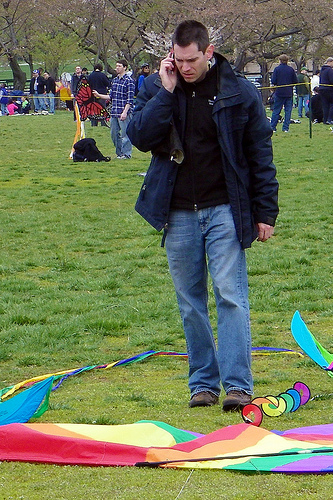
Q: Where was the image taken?
A: It was taken at the field.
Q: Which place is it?
A: It is a field.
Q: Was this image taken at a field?
A: Yes, it was taken in a field.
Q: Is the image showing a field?
A: Yes, it is showing a field.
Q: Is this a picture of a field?
A: Yes, it is showing a field.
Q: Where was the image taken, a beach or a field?
A: It was taken at a field.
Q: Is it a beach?
A: No, it is a field.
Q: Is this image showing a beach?
A: No, the picture is showing a field.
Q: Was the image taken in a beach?
A: No, the picture was taken in a field.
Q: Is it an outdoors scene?
A: Yes, it is outdoors.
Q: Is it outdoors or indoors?
A: It is outdoors.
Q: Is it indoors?
A: No, it is outdoors.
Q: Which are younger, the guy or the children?
A: The children are younger than the guy.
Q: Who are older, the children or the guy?
A: The guy are older than the children.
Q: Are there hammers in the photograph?
A: No, there are no hammers.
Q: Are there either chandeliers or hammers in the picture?
A: No, there are no hammers or chandeliers.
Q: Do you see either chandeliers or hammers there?
A: No, there are no hammers or chandeliers.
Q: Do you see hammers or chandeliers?
A: No, there are no hammers or chandeliers.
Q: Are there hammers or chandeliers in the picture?
A: No, there are no hammers or chandeliers.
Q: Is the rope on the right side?
A: Yes, the rope is on the right of the image.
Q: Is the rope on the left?
A: No, the rope is on the right of the image.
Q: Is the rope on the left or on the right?
A: The rope is on the right of the image.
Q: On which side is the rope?
A: The rope is on the right of the image.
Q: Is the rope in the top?
A: Yes, the rope is in the top of the image.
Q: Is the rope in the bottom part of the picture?
A: No, the rope is in the top of the image.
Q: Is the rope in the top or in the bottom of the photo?
A: The rope is in the top of the image.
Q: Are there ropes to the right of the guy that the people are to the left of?
A: Yes, there is a rope to the right of the guy.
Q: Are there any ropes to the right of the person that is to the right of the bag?
A: Yes, there is a rope to the right of the guy.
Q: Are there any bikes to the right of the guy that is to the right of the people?
A: No, there is a rope to the right of the guy.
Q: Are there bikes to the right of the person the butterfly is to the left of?
A: No, there is a rope to the right of the guy.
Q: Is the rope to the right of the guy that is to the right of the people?
A: Yes, the rope is to the right of the guy.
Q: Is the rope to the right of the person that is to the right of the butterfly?
A: Yes, the rope is to the right of the guy.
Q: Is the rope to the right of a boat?
A: No, the rope is to the right of the guy.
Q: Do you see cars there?
A: No, there are no cars.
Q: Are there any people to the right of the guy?
A: Yes, there are people to the right of the guy.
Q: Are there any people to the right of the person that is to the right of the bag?
A: Yes, there are people to the right of the guy.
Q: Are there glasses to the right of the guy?
A: No, there are people to the right of the guy.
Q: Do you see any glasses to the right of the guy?
A: No, there are people to the right of the guy.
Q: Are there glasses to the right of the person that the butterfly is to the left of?
A: No, there are people to the right of the guy.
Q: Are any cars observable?
A: No, there are no cars.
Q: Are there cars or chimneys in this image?
A: No, there are no cars or chimneys.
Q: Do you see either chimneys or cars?
A: No, there are no cars or chimneys.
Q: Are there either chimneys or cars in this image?
A: No, there are no cars or chimneys.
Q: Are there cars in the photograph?
A: No, there are no cars.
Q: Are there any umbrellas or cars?
A: No, there are no cars or umbrellas.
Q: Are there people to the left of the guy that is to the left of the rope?
A: Yes, there are people to the left of the guy.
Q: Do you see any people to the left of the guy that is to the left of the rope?
A: Yes, there are people to the left of the guy.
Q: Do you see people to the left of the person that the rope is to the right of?
A: Yes, there are people to the left of the guy.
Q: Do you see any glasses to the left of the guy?
A: No, there are people to the left of the guy.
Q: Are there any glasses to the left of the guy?
A: No, there are people to the left of the guy.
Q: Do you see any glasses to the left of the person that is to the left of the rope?
A: No, there are people to the left of the guy.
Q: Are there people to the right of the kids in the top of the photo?
A: Yes, there are people to the right of the children.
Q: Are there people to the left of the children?
A: No, the people are to the right of the children.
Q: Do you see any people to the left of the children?
A: No, the people are to the right of the children.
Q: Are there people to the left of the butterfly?
A: Yes, there are people to the left of the butterfly.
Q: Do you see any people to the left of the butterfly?
A: Yes, there are people to the left of the butterfly.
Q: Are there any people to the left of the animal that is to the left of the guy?
A: Yes, there are people to the left of the butterfly.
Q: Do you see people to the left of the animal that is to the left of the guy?
A: Yes, there are people to the left of the butterfly.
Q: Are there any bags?
A: Yes, there is a bag.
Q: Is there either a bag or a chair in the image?
A: Yes, there is a bag.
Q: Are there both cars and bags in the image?
A: No, there is a bag but no cars.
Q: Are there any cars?
A: No, there are no cars.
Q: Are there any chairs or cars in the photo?
A: No, there are no cars or chairs.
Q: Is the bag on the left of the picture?
A: Yes, the bag is on the left of the image.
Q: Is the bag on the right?
A: No, the bag is on the left of the image.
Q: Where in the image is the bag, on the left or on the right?
A: The bag is on the left of the image.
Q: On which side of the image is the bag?
A: The bag is on the left of the image.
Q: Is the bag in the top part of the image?
A: Yes, the bag is in the top of the image.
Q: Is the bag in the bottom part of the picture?
A: No, the bag is in the top of the image.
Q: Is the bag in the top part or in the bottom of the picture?
A: The bag is in the top of the image.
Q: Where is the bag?
A: The bag is on the ground.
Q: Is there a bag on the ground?
A: Yes, there is a bag on the ground.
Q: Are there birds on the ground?
A: No, there is a bag on the ground.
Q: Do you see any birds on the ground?
A: No, there is a bag on the ground.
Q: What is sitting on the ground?
A: The bag is sitting on the ground.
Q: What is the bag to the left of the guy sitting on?
A: The bag is sitting on the ground.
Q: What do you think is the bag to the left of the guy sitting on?
A: The bag is sitting on the ground.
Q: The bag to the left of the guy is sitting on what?
A: The bag is sitting on the ground.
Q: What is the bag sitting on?
A: The bag is sitting on the ground.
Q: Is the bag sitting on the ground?
A: Yes, the bag is sitting on the ground.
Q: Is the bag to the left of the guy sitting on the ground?
A: Yes, the bag is sitting on the ground.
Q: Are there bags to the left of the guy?
A: Yes, there is a bag to the left of the guy.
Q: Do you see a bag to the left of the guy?
A: Yes, there is a bag to the left of the guy.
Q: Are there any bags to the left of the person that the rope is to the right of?
A: Yes, there is a bag to the left of the guy.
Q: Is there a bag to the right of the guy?
A: No, the bag is to the left of the guy.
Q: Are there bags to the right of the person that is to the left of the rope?
A: No, the bag is to the left of the guy.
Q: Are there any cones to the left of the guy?
A: No, there is a bag to the left of the guy.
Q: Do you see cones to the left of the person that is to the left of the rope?
A: No, there is a bag to the left of the guy.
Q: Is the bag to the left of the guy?
A: Yes, the bag is to the left of the guy.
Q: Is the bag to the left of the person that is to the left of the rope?
A: Yes, the bag is to the left of the guy.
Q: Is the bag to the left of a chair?
A: No, the bag is to the left of the guy.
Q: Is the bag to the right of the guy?
A: No, the bag is to the left of the guy.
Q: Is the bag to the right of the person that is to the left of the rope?
A: No, the bag is to the left of the guy.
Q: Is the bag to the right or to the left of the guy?
A: The bag is to the left of the guy.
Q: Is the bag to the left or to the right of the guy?
A: The bag is to the left of the guy.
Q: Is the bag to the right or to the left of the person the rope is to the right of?
A: The bag is to the left of the guy.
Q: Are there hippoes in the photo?
A: No, there are no hippoes.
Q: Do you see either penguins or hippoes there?
A: No, there are no hippoes or penguins.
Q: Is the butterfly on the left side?
A: Yes, the butterfly is on the left of the image.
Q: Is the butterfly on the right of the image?
A: No, the butterfly is on the left of the image.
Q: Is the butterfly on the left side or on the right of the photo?
A: The butterfly is on the left of the image.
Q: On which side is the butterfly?
A: The butterfly is on the left of the image.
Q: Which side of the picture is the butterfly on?
A: The butterfly is on the left of the image.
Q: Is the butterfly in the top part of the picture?
A: Yes, the butterfly is in the top of the image.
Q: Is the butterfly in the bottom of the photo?
A: No, the butterfly is in the top of the image.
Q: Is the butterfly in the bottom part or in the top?
A: The butterfly is in the top of the image.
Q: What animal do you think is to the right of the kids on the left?
A: The animal is a butterfly.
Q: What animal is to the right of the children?
A: The animal is a butterfly.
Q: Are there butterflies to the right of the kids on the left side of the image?
A: Yes, there is a butterfly to the right of the kids.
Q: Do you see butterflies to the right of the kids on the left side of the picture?
A: Yes, there is a butterfly to the right of the kids.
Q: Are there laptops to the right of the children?
A: No, there is a butterfly to the right of the children.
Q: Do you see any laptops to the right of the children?
A: No, there is a butterfly to the right of the children.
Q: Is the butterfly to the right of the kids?
A: Yes, the butterfly is to the right of the kids.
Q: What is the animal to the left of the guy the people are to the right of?
A: The animal is a butterfly.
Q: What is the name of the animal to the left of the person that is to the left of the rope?
A: The animal is a butterfly.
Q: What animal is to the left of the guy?
A: The animal is a butterfly.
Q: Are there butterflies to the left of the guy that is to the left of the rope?
A: Yes, there is a butterfly to the left of the guy.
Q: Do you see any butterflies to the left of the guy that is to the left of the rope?
A: Yes, there is a butterfly to the left of the guy.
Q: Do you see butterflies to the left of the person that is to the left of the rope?
A: Yes, there is a butterfly to the left of the guy.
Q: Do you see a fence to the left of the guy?
A: No, there is a butterfly to the left of the guy.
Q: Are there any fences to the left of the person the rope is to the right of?
A: No, there is a butterfly to the left of the guy.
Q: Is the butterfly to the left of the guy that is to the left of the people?
A: Yes, the butterfly is to the left of the guy.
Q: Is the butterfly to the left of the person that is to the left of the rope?
A: Yes, the butterfly is to the left of the guy.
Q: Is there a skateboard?
A: No, there are no skateboards.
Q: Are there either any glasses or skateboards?
A: No, there are no skateboards or glasses.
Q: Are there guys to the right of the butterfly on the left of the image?
A: Yes, there is a guy to the right of the butterfly.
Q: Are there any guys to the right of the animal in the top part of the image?
A: Yes, there is a guy to the right of the butterfly.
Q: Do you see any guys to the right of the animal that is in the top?
A: Yes, there is a guy to the right of the butterfly.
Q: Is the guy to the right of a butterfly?
A: Yes, the guy is to the right of a butterfly.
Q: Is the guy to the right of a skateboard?
A: No, the guy is to the right of a butterfly.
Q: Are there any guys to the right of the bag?
A: Yes, there is a guy to the right of the bag.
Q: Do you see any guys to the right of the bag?
A: Yes, there is a guy to the right of the bag.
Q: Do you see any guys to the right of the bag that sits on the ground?
A: Yes, there is a guy to the right of the bag.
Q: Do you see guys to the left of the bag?
A: No, the guy is to the right of the bag.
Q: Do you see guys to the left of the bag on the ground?
A: No, the guy is to the right of the bag.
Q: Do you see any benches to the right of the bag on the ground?
A: No, there is a guy to the right of the bag.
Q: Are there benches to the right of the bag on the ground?
A: No, there is a guy to the right of the bag.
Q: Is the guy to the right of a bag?
A: Yes, the guy is to the right of a bag.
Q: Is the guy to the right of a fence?
A: No, the guy is to the right of a bag.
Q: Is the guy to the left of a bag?
A: No, the guy is to the right of a bag.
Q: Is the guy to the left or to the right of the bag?
A: The guy is to the right of the bag.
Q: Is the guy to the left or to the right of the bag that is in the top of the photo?
A: The guy is to the right of the bag.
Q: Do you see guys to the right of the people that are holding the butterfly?
A: Yes, there is a guy to the right of the people.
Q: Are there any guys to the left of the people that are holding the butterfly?
A: No, the guy is to the right of the people.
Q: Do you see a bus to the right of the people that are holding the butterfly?
A: No, there is a guy to the right of the people.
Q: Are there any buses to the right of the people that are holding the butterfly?
A: No, there is a guy to the right of the people.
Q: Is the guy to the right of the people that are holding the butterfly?
A: Yes, the guy is to the right of the people.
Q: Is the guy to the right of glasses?
A: No, the guy is to the right of the people.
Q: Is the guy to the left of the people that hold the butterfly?
A: No, the guy is to the right of the people.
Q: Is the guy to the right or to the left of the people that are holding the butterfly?
A: The guy is to the right of the people.